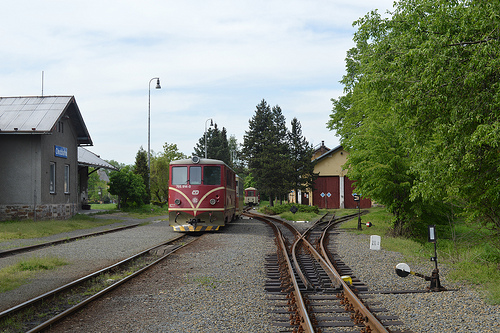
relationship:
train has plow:
[165, 155, 245, 233] [167, 206, 227, 233]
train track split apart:
[265, 215, 364, 296] [272, 215, 336, 229]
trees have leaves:
[326, 6, 499, 229] [380, 49, 469, 119]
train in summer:
[165, 155, 245, 233] [5, 4, 493, 333]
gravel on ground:
[198, 262, 263, 332] [104, 244, 234, 332]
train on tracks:
[165, 155, 245, 233] [119, 236, 189, 271]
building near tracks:
[1, 94, 93, 218] [119, 236, 189, 271]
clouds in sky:
[83, 5, 241, 76] [1, 1, 347, 133]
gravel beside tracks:
[198, 262, 263, 332] [119, 236, 189, 271]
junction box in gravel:
[430, 234, 444, 293] [198, 262, 263, 332]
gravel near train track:
[198, 262, 263, 332] [265, 215, 364, 296]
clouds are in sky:
[83, 5, 241, 76] [1, 1, 347, 133]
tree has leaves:
[326, 6, 499, 229] [380, 49, 469, 119]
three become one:
[245, 208, 376, 238] [278, 247, 349, 292]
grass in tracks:
[82, 261, 127, 288] [119, 236, 189, 271]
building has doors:
[307, 140, 363, 211] [306, 176, 371, 209]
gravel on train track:
[198, 262, 263, 332] [235, 207, 398, 331]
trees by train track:
[326, 6, 499, 229] [235, 207, 398, 331]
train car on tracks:
[165, 155, 245, 233] [119, 236, 189, 271]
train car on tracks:
[241, 184, 262, 205] [119, 236, 189, 271]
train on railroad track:
[165, 155, 245, 233] [119, 236, 189, 271]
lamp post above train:
[146, 78, 165, 99] [165, 155, 245, 233]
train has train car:
[165, 155, 245, 233] [244, 187, 260, 209]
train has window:
[165, 155, 245, 233] [173, 166, 221, 182]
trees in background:
[111, 146, 169, 212] [96, 127, 356, 204]